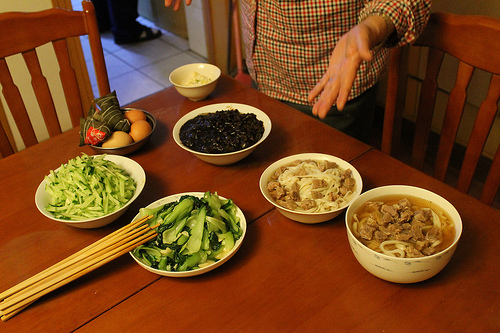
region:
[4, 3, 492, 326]
Table covered with plates of food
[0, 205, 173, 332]
Bunch of wooden chopsticks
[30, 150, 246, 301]
Two bowls of green vegetables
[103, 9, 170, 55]
Person's feet with black sandals and white socks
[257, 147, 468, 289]
Two bowls of soup with noodles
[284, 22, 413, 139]
Man's left hand outstretched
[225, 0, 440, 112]
Man wearing a striped long sleeve shirt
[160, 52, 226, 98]
Small white bowl with food in it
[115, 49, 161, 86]
Square tiles on the floor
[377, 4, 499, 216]
Wooden chair place at the table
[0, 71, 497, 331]
brown wooden table with food on it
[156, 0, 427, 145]
person standing next to table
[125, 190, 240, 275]
bowl with green vegetable in it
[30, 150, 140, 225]
bowl with green veggies in it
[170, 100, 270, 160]
bowl with black colored food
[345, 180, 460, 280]
large bowl of soup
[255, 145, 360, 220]
bowl with food in it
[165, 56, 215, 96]
small bowl with sauce in it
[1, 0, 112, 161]
brown wooden chair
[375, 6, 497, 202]
wooden chair next to table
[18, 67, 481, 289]
several bowls of different kinds of food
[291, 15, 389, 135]
a person's hand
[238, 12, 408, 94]
a person wearing a plaid shirt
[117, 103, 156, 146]
three eggs in a bowl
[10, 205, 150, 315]
several chop sticks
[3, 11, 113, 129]
a wooden chair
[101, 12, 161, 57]
a person's foot wearing a black shoe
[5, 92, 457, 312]
a wooden table with bowls of food on it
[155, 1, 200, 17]
a person's fingers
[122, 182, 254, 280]
a bowl full of broccoli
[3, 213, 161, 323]
Chop sticks placed on the bowl in the center.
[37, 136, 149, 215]
Bowl of chopped up greens to the left.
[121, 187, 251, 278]
Bowl of chopped up greens that the chopsticks are placed on.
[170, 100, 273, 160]
Bowl of dark liquid and particles.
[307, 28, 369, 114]
Full hand of the person standing at the table.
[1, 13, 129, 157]
Wooden chair facing the greens.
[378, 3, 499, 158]
Wooden chair facing the two bowls of meat substance soup.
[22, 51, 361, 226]
The left side of the table.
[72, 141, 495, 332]
The right side of the table.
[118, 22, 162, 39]
The black slipper on the foot of the person standing on the tiles.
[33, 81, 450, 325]
Bowls on the table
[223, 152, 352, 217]
Food on the table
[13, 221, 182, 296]
Chop sticks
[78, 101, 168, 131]
eggs on the table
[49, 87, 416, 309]
Toppings on the table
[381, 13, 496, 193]
Chair at the dinner table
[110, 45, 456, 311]
Ready to eat at the table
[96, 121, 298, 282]
Bowl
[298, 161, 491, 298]
White bowl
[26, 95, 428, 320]
Lots of food on the table for lunch